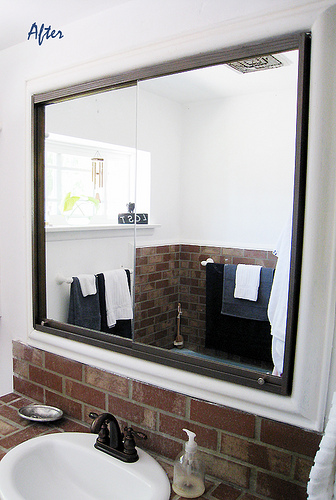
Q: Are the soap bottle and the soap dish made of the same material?
A: No, the soap bottle is made of plastic and the soap dish is made of metal.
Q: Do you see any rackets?
A: No, there are no rackets.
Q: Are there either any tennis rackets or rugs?
A: No, there are no tennis rackets or rugs.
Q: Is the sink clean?
A: Yes, the sink is clean.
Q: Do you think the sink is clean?
A: Yes, the sink is clean.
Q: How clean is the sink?
A: The sink is clean.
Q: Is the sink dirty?
A: No, the sink is clean.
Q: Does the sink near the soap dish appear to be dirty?
A: No, the sink is clean.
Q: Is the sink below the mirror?
A: Yes, the sink is below the mirror.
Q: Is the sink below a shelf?
A: No, the sink is below the mirror.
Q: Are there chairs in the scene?
A: No, there are no chairs.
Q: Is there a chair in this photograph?
A: No, there are no chairs.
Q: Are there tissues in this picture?
A: No, there are no tissues.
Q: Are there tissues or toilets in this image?
A: No, there are no tissues or toilets.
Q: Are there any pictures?
A: No, there are no pictures.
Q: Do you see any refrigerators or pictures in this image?
A: No, there are no pictures or refrigerators.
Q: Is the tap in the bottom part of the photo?
A: Yes, the tap is in the bottom of the image.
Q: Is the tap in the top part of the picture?
A: No, the tap is in the bottom of the image.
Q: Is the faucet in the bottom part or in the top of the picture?
A: The faucet is in the bottom of the image.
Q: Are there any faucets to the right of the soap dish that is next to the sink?
A: Yes, there is a faucet to the right of the soap dish.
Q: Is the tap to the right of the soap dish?
A: Yes, the tap is to the right of the soap dish.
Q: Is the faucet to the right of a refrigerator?
A: No, the faucet is to the right of the soap dish.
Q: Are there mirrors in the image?
A: Yes, there is a mirror.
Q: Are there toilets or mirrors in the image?
A: Yes, there is a mirror.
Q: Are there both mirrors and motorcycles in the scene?
A: No, there is a mirror but no motorcycles.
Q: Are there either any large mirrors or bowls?
A: Yes, there is a large mirror.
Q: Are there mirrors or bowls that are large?
A: Yes, the mirror is large.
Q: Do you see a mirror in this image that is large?
A: Yes, there is a large mirror.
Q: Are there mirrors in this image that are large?
A: Yes, there is a mirror that is large.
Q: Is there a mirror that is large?
A: Yes, there is a mirror that is large.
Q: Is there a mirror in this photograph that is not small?
A: Yes, there is a large mirror.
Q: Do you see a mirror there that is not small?
A: Yes, there is a large mirror.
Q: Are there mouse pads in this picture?
A: No, there are no mouse pads.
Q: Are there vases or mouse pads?
A: No, there are no mouse pads or vases.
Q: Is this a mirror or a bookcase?
A: This is a mirror.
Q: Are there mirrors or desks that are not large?
A: No, there is a mirror but it is large.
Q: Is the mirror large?
A: Yes, the mirror is large.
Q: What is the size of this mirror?
A: The mirror is large.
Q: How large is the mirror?
A: The mirror is large.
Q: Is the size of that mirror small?
A: No, the mirror is large.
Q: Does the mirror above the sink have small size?
A: No, the mirror is large.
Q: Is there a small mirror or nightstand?
A: No, there is a mirror but it is large.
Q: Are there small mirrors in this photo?
A: No, there is a mirror but it is large.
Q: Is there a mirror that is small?
A: No, there is a mirror but it is large.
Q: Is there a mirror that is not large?
A: No, there is a mirror but it is large.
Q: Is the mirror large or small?
A: The mirror is large.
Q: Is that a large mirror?
A: Yes, that is a large mirror.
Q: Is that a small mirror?
A: No, that is a large mirror.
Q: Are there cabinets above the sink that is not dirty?
A: No, there is a mirror above the sink.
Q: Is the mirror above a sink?
A: Yes, the mirror is above a sink.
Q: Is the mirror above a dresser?
A: No, the mirror is above a sink.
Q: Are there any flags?
A: No, there are no flags.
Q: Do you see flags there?
A: No, there are no flags.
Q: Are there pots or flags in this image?
A: No, there are no flags or pots.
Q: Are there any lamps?
A: No, there are no lamps.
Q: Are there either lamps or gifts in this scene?
A: No, there are no lamps or gifts.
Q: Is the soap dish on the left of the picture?
A: Yes, the soap dish is on the left of the image.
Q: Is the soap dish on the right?
A: No, the soap dish is on the left of the image.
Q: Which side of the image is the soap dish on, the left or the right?
A: The soap dish is on the left of the image.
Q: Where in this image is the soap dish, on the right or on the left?
A: The soap dish is on the left of the image.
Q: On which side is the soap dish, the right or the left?
A: The soap dish is on the left of the image.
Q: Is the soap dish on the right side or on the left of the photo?
A: The soap dish is on the left of the image.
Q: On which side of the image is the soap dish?
A: The soap dish is on the left of the image.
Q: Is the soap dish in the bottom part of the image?
A: Yes, the soap dish is in the bottom of the image.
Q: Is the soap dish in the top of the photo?
A: No, the soap dish is in the bottom of the image.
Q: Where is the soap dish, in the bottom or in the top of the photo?
A: The soap dish is in the bottom of the image.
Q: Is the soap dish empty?
A: Yes, the soap dish is empty.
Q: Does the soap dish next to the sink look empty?
A: Yes, the soap dish is empty.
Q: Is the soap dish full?
A: No, the soap dish is empty.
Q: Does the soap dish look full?
A: No, the soap dish is empty.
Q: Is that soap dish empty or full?
A: The soap dish is empty.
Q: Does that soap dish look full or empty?
A: The soap dish is empty.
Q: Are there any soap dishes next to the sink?
A: Yes, there is a soap dish next to the sink.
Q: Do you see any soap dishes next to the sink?
A: Yes, there is a soap dish next to the sink.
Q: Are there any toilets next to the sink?
A: No, there is a soap dish next to the sink.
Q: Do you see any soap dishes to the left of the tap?
A: Yes, there is a soap dish to the left of the tap.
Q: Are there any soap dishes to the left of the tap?
A: Yes, there is a soap dish to the left of the tap.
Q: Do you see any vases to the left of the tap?
A: No, there is a soap dish to the left of the tap.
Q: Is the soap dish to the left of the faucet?
A: Yes, the soap dish is to the left of the faucet.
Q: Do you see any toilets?
A: No, there are no toilets.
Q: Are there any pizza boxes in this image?
A: No, there are no pizza boxes.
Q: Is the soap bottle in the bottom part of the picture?
A: Yes, the soap bottle is in the bottom of the image.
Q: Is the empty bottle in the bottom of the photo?
A: Yes, the soap bottle is in the bottom of the image.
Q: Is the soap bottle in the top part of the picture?
A: No, the soap bottle is in the bottom of the image.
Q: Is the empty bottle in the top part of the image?
A: No, the soap bottle is in the bottom of the image.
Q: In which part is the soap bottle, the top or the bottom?
A: The soap bottle is in the bottom of the image.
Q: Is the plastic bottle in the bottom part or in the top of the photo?
A: The soap bottle is in the bottom of the image.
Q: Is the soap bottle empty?
A: Yes, the soap bottle is empty.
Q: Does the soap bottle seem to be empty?
A: Yes, the soap bottle is empty.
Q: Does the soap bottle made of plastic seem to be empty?
A: Yes, the soap bottle is empty.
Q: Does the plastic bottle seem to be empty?
A: Yes, the soap bottle is empty.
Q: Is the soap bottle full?
A: No, the soap bottle is empty.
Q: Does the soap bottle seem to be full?
A: No, the soap bottle is empty.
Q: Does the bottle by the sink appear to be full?
A: No, the soap bottle is empty.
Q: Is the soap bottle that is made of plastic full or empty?
A: The soap bottle is empty.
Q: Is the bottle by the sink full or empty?
A: The soap bottle is empty.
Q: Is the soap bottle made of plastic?
A: Yes, the soap bottle is made of plastic.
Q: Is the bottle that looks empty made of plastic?
A: Yes, the soap bottle is made of plastic.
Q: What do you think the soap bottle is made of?
A: The soap bottle is made of plastic.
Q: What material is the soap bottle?
A: The soap bottle is made of plastic.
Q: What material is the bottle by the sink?
A: The soap bottle is made of plastic.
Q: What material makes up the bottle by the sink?
A: The soap bottle is made of plastic.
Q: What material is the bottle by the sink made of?
A: The soap bottle is made of plastic.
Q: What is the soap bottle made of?
A: The soap bottle is made of plastic.